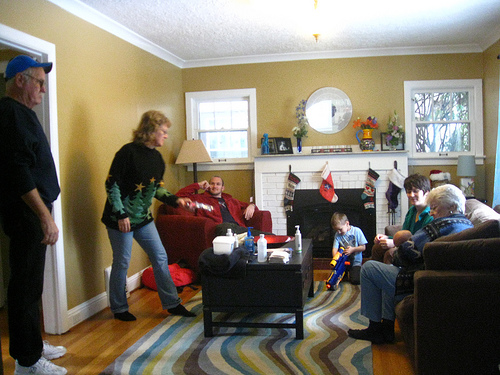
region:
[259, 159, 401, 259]
holiday stockings hung in front of a fireplace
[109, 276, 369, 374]
a rug with a wavy striped pattern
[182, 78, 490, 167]
two windows on opposite sides of a wall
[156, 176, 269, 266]
man sitting in a large red chair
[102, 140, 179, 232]
woman wearing a Christmas sweater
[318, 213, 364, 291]
boy playing with a toy gun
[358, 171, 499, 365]
two women sitting on a couch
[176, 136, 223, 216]
lamp behind man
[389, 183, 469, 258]
older woman holding a baby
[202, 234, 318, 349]
black box-like table on rug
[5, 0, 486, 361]
Christmas scene in a living room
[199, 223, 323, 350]
dark brown wooden coffee table with gifts on it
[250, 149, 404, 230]
white mantel around fireplace with four stockings on it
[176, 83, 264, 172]
window with white wood frame in fireplace wall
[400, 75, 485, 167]
window with white wood frame in fireplace wall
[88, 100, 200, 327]
woman with blond hair wearing jeans and a sweater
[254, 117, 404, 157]
knick knacks sitting on white wooden mantel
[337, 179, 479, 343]
woman with short gray hair and a blue shirt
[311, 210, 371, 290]
young boy with light blue shirt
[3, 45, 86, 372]
man with sneakers, black pants and black shirt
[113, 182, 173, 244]
Christmas trees on person's sweater.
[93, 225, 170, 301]
Person wearing blue jeans.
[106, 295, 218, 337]
Person wearing black socks.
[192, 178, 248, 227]
Person wearing red jacket.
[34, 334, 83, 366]
Person wearing white shoes.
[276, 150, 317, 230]
Stocking hanging from mantle.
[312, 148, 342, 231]
Stocking hanging from mantle.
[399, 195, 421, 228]
Person wearing green shirt.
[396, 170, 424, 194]
Person has dark hair.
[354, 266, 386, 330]
Person wearing blue pants.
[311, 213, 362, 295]
The child has a squirtgun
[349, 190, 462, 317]
The grandmother holds a child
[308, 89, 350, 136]
The window is circular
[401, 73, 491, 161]
The window is square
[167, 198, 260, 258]
The chair is red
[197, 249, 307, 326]
The table is black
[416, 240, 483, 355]
The couch is brown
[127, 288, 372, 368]
Table sits on a rug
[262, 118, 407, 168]
Many items on the fireplace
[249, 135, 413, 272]
The fireplace holds stockings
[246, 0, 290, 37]
part of a ceiling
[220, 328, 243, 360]
part of a carpet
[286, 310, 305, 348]
part of a stand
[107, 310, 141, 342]
part of a floor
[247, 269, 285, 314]
part of a table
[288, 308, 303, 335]
part of a stand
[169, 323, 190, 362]
part of a carpet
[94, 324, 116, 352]
part of a floor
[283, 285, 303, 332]
edge of a table